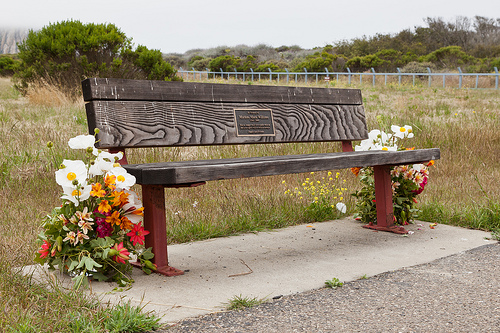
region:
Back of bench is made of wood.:
[100, 71, 381, 132]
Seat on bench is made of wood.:
[136, 137, 446, 188]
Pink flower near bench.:
[126, 219, 153, 241]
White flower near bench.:
[73, 246, 95, 265]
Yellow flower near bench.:
[107, 188, 139, 208]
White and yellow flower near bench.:
[58, 165, 95, 197]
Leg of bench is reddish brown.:
[142, 189, 195, 276]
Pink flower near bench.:
[413, 173, 430, 200]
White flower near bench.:
[333, 190, 349, 212]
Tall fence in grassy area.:
[248, 53, 498, 98]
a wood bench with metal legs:
[93, 54, 441, 308]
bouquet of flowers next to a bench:
[29, 114, 166, 326]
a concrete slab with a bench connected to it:
[15, 199, 486, 331]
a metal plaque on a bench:
[224, 85, 289, 142]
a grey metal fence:
[331, 58, 496, 85]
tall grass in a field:
[0, 77, 490, 174]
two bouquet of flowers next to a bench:
[40, 106, 444, 301]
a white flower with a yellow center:
[41, 155, 86, 201]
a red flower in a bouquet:
[119, 214, 148, 258]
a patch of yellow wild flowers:
[276, 167, 350, 233]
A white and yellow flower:
[51, 159, 83, 185]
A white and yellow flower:
[105, 170, 135, 189]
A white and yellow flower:
[391, 123, 410, 139]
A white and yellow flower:
[413, 161, 425, 189]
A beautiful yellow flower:
[90, 183, 105, 195]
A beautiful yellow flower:
[106, 210, 119, 225]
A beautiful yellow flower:
[114, 192, 131, 206]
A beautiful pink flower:
[130, 226, 148, 239]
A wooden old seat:
[78, 63, 438, 264]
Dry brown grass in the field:
[439, 97, 491, 206]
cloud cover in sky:
[1, 1, 494, 48]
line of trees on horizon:
[166, 44, 338, 69]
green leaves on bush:
[1, 19, 178, 97]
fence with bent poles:
[178, 68, 498, 86]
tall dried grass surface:
[1, 84, 496, 330]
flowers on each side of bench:
[41, 79, 439, 282]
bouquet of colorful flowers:
[39, 131, 151, 280]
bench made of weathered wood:
[81, 76, 438, 274]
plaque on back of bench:
[233, 106, 277, 137]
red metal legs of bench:
[134, 166, 407, 276]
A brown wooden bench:
[80, 75, 440, 279]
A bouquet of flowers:
[35, 133, 157, 298]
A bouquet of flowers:
[347, 119, 442, 229]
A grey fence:
[165, 59, 498, 91]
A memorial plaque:
[228, 105, 280, 140]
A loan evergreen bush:
[6, 18, 185, 98]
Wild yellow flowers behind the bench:
[280, 170, 346, 208]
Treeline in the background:
[165, 15, 496, 67]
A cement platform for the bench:
[8, 197, 493, 327]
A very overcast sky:
[2, 15, 498, 49]